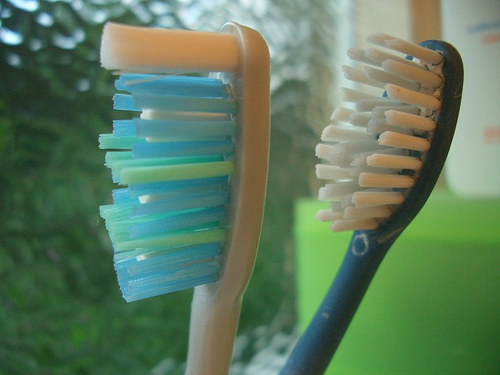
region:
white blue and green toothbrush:
[70, 6, 280, 341]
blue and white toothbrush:
[269, 24, 471, 373]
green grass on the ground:
[402, 237, 477, 347]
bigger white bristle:
[87, 20, 241, 75]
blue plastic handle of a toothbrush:
[277, 232, 382, 372]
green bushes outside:
[4, 38, 99, 355]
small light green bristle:
[115, 159, 236, 191]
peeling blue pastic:
[346, 227, 374, 263]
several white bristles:
[301, 30, 480, 237]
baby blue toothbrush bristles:
[115, 114, 224, 145]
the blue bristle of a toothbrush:
[134, 185, 227, 209]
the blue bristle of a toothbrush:
[126, 241, 223, 267]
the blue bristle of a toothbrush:
[124, 266, 224, 281]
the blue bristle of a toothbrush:
[129, 74, 227, 96]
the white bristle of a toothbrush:
[97, 19, 245, 76]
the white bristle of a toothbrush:
[377, 130, 425, 151]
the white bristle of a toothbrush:
[366, 150, 422, 170]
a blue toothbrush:
[280, 31, 460, 373]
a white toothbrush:
[90, 17, 266, 374]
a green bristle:
[110, 226, 225, 252]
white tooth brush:
[93, 15, 267, 374]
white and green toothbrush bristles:
[99, 22, 235, 306]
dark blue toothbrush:
[280, 33, 452, 373]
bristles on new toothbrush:
[101, 16, 263, 316]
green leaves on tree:
[1, 1, 298, 372]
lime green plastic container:
[296, 194, 499, 372]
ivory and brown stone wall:
[353, 1, 443, 196]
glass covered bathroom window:
[1, 1, 325, 374]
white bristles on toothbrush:
[311, 32, 441, 231]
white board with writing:
[443, 2, 498, 192]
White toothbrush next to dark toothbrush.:
[206, 39, 253, 373]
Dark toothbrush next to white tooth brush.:
[306, 150, 351, 365]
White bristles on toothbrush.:
[346, 100, 376, 187]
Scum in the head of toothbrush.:
[409, 70, 434, 190]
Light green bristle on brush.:
[132, 165, 232, 187]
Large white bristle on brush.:
[94, 8, 234, 85]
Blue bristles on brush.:
[112, 118, 237, 167]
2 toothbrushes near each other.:
[17, 105, 448, 335]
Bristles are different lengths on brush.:
[318, 71, 390, 204]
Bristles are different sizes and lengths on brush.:
[96, 67, 156, 280]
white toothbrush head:
[83, 12, 271, 365]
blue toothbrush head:
[280, 27, 471, 367]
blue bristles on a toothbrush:
[116, 257, 230, 300]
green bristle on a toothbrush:
[101, 201, 228, 254]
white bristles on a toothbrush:
[314, 135, 401, 229]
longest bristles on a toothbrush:
[94, 18, 239, 73]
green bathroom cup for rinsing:
[432, 189, 488, 359]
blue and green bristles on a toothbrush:
[82, 103, 186, 270]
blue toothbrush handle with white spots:
[308, 225, 414, 287]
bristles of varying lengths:
[93, 52, 181, 324]